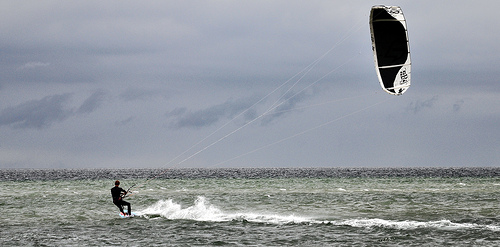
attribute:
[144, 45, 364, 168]
strings — white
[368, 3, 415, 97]
kite — black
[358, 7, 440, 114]
kite — white, black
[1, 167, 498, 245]
water — blue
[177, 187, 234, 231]
water — white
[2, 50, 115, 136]
cloud — white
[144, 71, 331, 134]
cloud — white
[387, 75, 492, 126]
cloud — white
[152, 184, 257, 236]
splash — small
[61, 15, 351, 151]
sky — blue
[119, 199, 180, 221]
surfing — sea